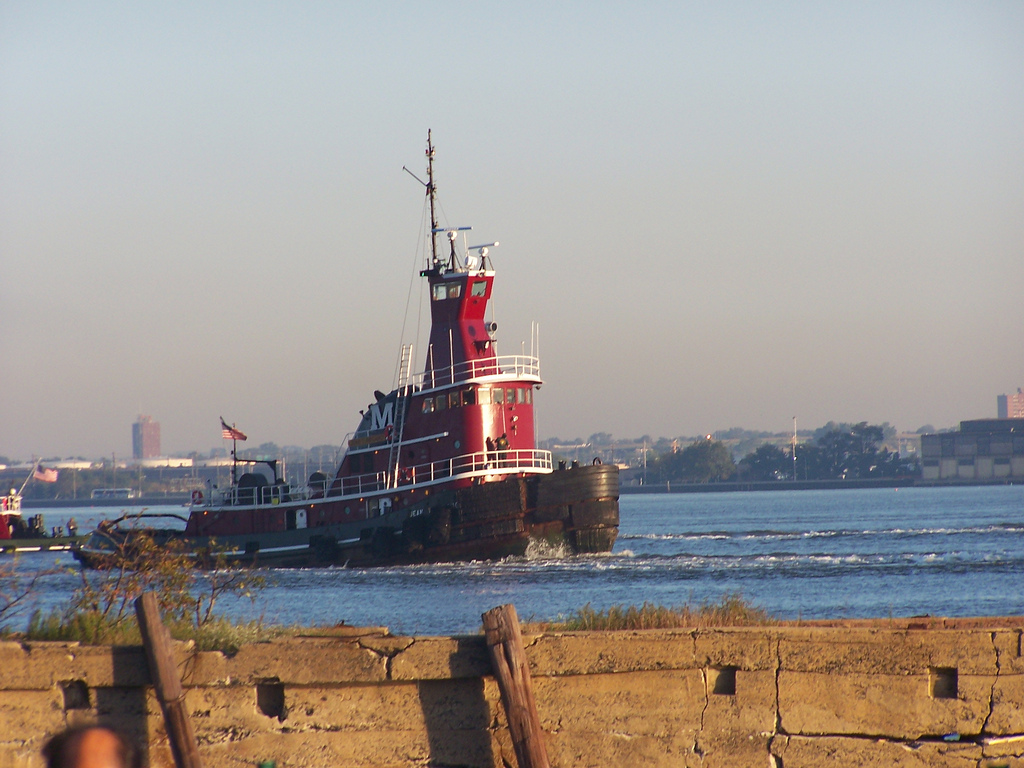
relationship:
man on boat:
[412, 460, 436, 486] [64, 127, 619, 576]